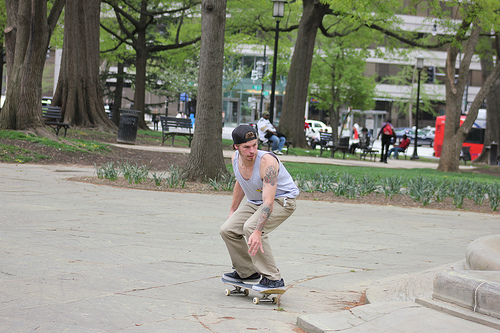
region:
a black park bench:
[144, 95, 202, 174]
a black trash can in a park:
[84, 85, 162, 167]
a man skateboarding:
[180, 93, 330, 298]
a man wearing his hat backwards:
[208, 105, 265, 190]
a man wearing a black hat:
[191, 110, 261, 175]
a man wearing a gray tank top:
[193, 110, 313, 224]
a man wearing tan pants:
[191, 108, 299, 297]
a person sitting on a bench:
[239, 105, 322, 159]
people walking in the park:
[315, 104, 426, 172]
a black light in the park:
[248, 0, 303, 163]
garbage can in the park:
[113, 103, 140, 145]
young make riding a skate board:
[220, 124, 301, 311]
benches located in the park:
[36, 101, 375, 154]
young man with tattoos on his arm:
[222, 124, 301, 292]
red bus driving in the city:
[434, 113, 499, 170]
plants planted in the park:
[96, 158, 496, 212]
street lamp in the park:
[266, 1, 286, 131]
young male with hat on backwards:
[221, 126, 298, 306]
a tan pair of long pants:
[218, 197, 298, 280]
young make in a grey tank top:
[219, 123, 300, 291]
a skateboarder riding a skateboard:
[171, 112, 311, 313]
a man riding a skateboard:
[170, 110, 315, 315]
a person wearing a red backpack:
[375, 112, 400, 166]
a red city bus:
[427, 106, 494, 166]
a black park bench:
[151, 108, 197, 147]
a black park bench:
[39, 101, 70, 132]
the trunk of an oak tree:
[3, 52, 49, 129]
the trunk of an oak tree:
[51, 71, 113, 133]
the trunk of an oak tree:
[169, 98, 229, 183]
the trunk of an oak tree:
[273, 82, 311, 148]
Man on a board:
[216, 274, 291, 311]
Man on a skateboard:
[219, 270, 292, 311]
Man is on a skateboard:
[220, 270, 293, 309]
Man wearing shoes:
[217, 267, 288, 291]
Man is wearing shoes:
[219, 268, 288, 298]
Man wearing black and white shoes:
[220, 262, 291, 292]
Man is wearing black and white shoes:
[217, 262, 290, 294]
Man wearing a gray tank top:
[230, 143, 300, 204]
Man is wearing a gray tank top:
[227, 145, 302, 207]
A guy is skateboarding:
[216, 121, 301, 308]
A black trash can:
[114, 110, 142, 149]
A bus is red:
[430, 112, 490, 163]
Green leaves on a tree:
[308, 45, 378, 146]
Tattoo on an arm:
[260, 160, 282, 190]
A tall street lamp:
[267, 0, 287, 125]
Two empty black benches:
[37, 102, 198, 149]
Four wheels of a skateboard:
[222, 286, 280, 306]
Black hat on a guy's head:
[228, 121, 261, 165]